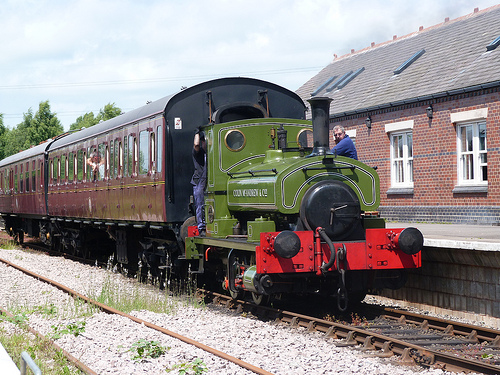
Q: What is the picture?
A: Train.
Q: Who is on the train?
A: Men.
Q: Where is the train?
A: On the tracks.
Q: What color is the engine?
A: Green.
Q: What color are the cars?
A: Red.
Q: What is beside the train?
A: Building.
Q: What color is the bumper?
A: Red.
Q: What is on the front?
A: Smoke stack.